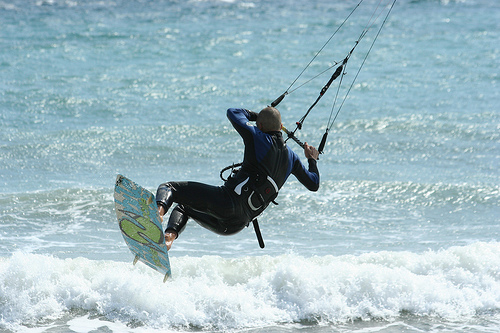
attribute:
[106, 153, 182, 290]
board — blue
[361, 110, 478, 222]
water — with Ripples, calm, wavy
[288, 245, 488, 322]
wave — foaming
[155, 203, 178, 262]
feet — bare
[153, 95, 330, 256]
man — kite surfing, parasailing, holding on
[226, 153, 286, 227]
harness — black, blue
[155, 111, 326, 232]
wetsuit — black, blue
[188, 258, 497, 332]
waves — breaking, small